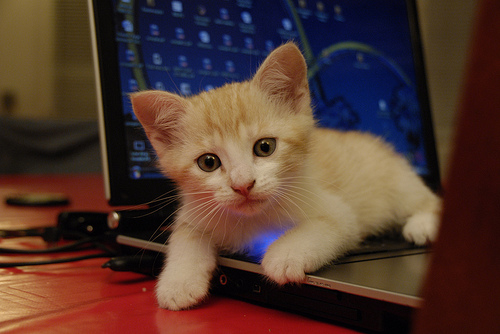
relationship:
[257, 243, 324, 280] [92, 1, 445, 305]
cat's paw on laptop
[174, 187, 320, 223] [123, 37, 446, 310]
kittys whiskers on cat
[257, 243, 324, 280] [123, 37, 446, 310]
cat's paw on cat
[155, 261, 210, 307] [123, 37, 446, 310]
paw on cat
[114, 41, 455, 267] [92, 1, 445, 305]
cat on laptop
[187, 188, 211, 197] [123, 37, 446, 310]
kittys whiskers of cat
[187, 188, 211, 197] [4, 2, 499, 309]
kittys whiskers on background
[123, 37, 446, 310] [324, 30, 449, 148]
cat sitting on top laptop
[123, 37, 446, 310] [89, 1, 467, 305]
cat on computer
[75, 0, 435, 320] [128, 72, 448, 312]
computer with kitten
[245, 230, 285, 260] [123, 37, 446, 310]
light under cat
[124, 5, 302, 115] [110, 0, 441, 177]
icons on screen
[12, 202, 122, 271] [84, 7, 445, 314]
cords from computer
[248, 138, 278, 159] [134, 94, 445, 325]
eye of kitty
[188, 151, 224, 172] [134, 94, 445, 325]
eye of kitty